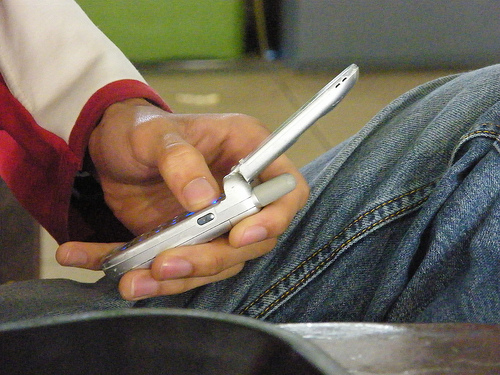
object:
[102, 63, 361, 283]
cell phone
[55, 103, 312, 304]
hand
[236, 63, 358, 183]
top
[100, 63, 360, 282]
side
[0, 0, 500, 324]
person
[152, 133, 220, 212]
thumb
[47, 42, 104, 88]
part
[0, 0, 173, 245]
sleeve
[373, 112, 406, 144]
part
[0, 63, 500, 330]
jeans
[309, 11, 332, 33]
part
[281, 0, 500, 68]
wall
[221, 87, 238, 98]
part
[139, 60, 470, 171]
ground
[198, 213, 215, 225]
button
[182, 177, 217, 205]
nail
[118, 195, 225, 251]
light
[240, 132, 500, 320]
hem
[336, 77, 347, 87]
tiny opening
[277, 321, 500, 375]
table